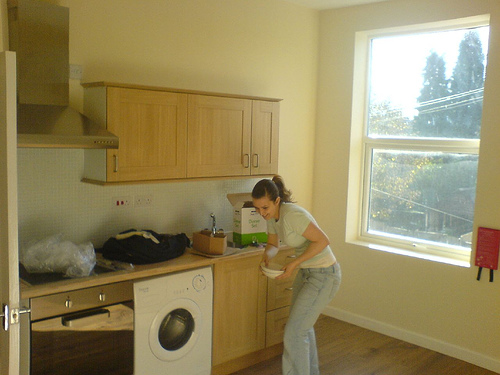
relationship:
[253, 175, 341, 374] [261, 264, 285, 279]
woman holding bowl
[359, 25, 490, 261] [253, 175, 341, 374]
window behind woman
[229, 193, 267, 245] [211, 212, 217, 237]
box next to faucet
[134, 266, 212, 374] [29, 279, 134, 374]
washer next to dishwasher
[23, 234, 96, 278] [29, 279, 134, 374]
bag on top of dishwasher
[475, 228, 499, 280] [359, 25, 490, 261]
sign next to window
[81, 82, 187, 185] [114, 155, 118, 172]
cabinet has handle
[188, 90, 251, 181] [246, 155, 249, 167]
cabinet has handle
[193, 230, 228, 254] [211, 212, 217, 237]
cardboard next to faucet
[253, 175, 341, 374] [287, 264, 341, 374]
woman wearing jeans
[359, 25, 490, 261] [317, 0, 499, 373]
window on wall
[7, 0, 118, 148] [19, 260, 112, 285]
vent above stove top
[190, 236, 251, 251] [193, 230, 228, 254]
sink under cardboard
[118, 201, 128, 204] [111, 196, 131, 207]
switch has plate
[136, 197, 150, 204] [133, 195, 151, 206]
outlet has plate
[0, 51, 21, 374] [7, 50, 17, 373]
door has edge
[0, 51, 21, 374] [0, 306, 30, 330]
door has handle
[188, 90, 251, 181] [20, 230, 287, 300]
cabinet are above counter top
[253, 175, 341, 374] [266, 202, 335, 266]
woman wearing shirt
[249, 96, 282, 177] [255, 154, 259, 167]
cabinet has handle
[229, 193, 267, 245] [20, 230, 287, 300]
box on top of counter top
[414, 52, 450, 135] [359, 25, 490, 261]
tree outside of window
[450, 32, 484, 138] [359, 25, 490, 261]
tree outside of window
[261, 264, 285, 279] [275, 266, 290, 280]
bowl inside hand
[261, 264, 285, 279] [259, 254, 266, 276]
bowl inside hand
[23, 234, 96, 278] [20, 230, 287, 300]
bag on top counter top